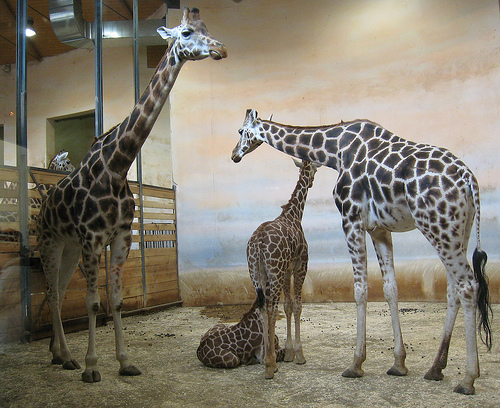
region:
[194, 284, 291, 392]
small giraffe on the ground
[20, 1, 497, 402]
a family of giraffe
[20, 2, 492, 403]
four giraffes in an enclosure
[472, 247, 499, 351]
black hair on a giraffes tail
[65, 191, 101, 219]
brown spots on a giraffe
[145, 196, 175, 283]
wooden enclosure wall on a giraffe pen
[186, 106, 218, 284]
mural of a sunset on the wall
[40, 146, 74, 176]
head of a giraffe from a nearby enclosure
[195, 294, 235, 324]
stain on the floor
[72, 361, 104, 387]
hoof of a giraffe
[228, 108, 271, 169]
face of the giraffe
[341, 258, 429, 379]
front legs of giraffe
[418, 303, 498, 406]
back two legs of giraffe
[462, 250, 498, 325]
tail of the giraffe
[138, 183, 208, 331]
a big wooden wall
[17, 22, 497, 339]
a ground of giraffe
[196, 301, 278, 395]
a giraffe sitting in ground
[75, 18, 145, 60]
a white light in wall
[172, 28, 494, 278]
a beautiful clean wall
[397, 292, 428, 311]
a small dust in ground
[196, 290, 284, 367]
A baby giraffe is lying down.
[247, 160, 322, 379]
A baby giraffe is standing up.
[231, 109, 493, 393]
A giraffe is standing over two baby giraffes.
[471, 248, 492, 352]
Black hair on the end of a giraffes tail.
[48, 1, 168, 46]
A silver air duct on the ceiling.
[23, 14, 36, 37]
A light is on on the ceiling.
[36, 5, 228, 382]
A giraffe is standing taller than all the rest.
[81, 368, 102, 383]
The giraffe has a clove-hoof.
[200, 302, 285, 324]
Wet area on the floor behing giraffes.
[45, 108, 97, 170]
Hallway door leading out of the room.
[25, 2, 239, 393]
fake giraffe in a pen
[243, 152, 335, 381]
fake giraffe in a pen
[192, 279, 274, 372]
fake giraffe in a pen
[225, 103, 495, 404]
fake giraffe in a pen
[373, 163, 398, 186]
brown spot on fake giraffe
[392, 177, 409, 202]
brown spot on fake giraffe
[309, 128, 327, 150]
brown spot on fake giraffe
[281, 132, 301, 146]
brown spot on fake giraffe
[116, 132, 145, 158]
brown spot on fake giraffe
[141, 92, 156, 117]
brown spot on fake giraffe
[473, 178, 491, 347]
The tail of the giraffe on the right.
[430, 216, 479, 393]
The back legs of the giraffe on the right.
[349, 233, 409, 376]
The front legs of the giraffe on the right.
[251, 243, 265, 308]
The tail of the giraffe in the middle.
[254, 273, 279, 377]
The back legs of the giraffe in the middle.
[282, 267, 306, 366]
The front legs of the giraffe in the middle.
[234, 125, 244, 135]
The eye of the giraffe on the right.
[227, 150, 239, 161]
The mouth of the giraffe on the right.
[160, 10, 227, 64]
The head of the giraffe on the left.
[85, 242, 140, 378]
The front legs of the giraffe on the left.